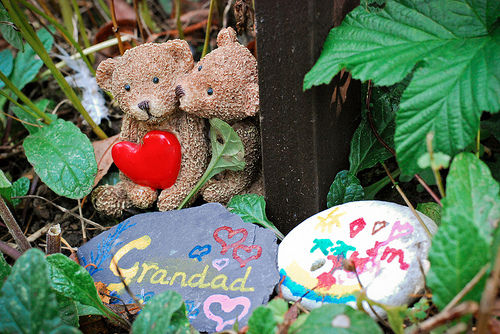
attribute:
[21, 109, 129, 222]
leaves — green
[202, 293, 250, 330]
heart — pink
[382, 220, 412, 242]
heart — pink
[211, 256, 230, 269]
heart — pink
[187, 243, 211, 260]
heart — blue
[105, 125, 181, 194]
heart — red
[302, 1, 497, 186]
leaf — large, overhanging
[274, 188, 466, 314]
stone — white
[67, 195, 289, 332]
stone — blue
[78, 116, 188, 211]
symbol — red, heart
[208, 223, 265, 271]
hearts — red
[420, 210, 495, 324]
leaf — green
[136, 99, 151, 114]
nose — black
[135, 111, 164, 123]
mouth — black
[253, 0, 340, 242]
post — brown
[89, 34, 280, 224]
bears — Brown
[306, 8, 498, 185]
leaves — green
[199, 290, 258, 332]
heart — pink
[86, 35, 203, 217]
teddy bear — brown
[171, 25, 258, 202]
teddy bear — brown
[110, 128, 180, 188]
heart — red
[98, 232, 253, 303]
word — yellow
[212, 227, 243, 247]
heart — red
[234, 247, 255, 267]
heart — red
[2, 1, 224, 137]
grass — green